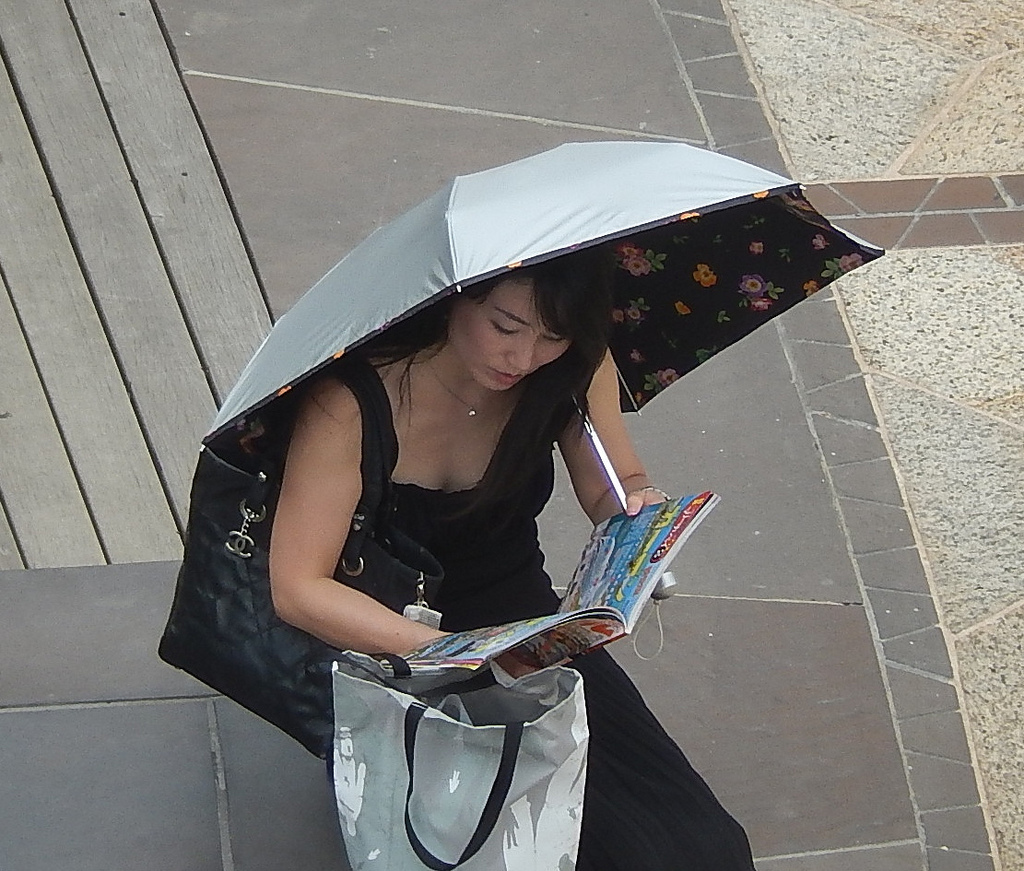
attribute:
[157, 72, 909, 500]
umbrella — Silver , black 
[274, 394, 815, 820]
dress — black 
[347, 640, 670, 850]
bag — gray , white 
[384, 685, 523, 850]
handles — black 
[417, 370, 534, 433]
neacklace — thin 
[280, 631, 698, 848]
bag — White 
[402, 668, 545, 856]
strap — black 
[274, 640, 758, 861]
purse — black 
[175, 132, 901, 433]
umbrella — black , silver 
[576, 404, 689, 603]
pole — Metal 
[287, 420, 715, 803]
dress — Black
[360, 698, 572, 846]
strap — Black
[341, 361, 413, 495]
strap — black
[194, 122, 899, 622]
umbrella — silver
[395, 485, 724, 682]
magazine — colorful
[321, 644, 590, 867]
bag — gray, white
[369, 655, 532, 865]
handles — black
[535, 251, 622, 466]
hair — dark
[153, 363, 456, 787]
bag — black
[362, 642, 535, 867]
handles — black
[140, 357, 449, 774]
purse — black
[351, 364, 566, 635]
shirt — black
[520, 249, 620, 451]
hair — dark